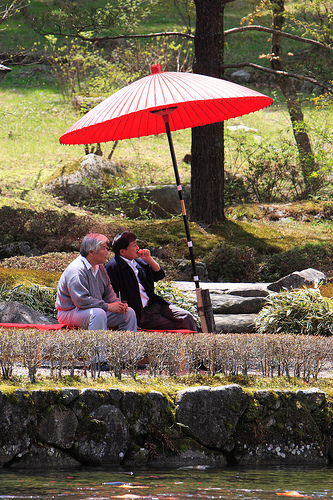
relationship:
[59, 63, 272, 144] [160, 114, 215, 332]
umbrella on stick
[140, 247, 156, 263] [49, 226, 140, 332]
hand of a person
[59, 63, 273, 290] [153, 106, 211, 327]
umbrella on top of stick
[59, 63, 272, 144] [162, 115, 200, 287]
umbrella on top of stick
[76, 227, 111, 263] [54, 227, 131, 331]
head of person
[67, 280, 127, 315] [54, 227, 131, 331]
arm on person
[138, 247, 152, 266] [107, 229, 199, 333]
hand on man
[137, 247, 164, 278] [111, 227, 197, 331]
arm of person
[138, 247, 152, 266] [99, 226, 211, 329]
hand of person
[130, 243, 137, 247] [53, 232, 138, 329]
eye on person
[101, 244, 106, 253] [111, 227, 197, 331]
eye on person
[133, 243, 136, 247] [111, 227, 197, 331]
eye on person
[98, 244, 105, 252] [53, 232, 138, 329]
eye on person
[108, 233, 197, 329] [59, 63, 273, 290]
man under umbrella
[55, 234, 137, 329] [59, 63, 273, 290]
man under umbrella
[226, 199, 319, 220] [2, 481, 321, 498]
water in river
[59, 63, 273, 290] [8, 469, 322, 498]
umbrella in river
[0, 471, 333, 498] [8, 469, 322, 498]
water in river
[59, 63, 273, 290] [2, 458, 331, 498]
umbrella next to water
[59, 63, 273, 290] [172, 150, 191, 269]
umbrella on stick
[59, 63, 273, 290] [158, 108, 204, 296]
umbrella on stick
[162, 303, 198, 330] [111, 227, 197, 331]
leg of person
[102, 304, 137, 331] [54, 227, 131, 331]
leg of person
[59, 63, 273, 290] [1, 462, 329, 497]
umbrella on river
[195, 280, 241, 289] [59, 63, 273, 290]
water on umbrella